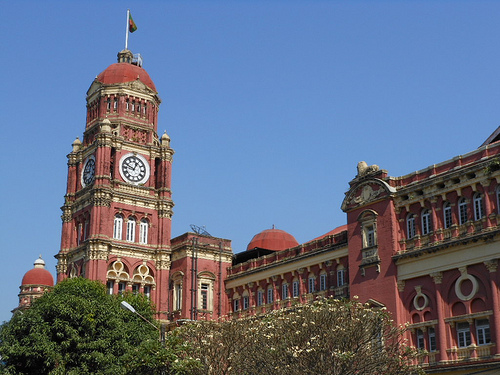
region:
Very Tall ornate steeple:
[48, 6, 176, 326]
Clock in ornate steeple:
[113, 151, 155, 184]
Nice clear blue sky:
[196, 5, 289, 53]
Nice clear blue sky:
[400, 31, 482, 127]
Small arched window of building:
[359, 217, 383, 251]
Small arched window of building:
[196, 276, 214, 313]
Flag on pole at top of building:
[116, 8, 141, 45]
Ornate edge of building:
[235, 248, 298, 265]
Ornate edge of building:
[404, 176, 476, 197]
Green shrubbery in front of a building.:
[6, 272, 170, 374]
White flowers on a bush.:
[162, 295, 397, 373]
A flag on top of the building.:
[116, 0, 138, 52]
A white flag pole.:
[122, 10, 130, 55]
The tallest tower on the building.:
[54, 55, 183, 315]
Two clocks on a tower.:
[60, 126, 174, 201]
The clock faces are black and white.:
[71, 145, 156, 189]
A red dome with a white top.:
[16, 253, 59, 307]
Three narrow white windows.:
[98, 203, 159, 246]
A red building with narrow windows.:
[232, 153, 495, 373]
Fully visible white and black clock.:
[118, 149, 148, 188]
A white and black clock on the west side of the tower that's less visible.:
[76, 156, 96, 188]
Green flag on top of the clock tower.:
[123, 9, 139, 33]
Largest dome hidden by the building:
[243, 225, 302, 254]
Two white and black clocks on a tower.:
[78, 154, 150, 184]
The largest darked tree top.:
[2, 272, 160, 373]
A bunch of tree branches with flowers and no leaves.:
[158, 294, 423, 374]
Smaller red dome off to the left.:
[19, 265, 53, 286]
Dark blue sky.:
[1, 2, 496, 232]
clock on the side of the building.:
[117, 148, 152, 188]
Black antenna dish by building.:
[177, 215, 215, 322]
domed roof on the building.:
[15, 250, 57, 290]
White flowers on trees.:
[165, 291, 411, 373]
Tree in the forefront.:
[1, 273, 182, 374]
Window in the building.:
[193, 269, 217, 313]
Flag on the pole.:
[117, 9, 144, 54]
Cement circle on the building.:
[452, 267, 478, 298]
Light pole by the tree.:
[117, 295, 163, 342]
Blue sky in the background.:
[0, 1, 496, 320]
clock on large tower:
[113, 147, 160, 198]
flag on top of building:
[110, 9, 149, 42]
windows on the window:
[457, 327, 469, 346]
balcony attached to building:
[452, 346, 497, 356]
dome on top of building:
[244, 225, 296, 252]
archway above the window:
[113, 212, 128, 242]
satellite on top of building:
[175, 214, 217, 248]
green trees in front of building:
[2, 282, 162, 370]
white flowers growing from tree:
[197, 293, 417, 373]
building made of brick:
[348, 215, 400, 282]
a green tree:
[24, 287, 131, 365]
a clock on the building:
[118, 149, 150, 184]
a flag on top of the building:
[124, 12, 139, 35]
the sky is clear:
[272, 70, 337, 122]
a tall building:
[52, 15, 177, 270]